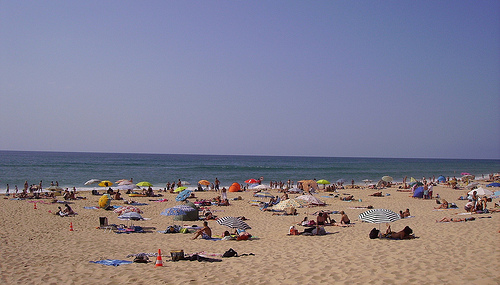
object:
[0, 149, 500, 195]
water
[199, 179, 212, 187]
umbrella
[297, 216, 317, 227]
person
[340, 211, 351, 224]
person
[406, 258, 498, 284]
sand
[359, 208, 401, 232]
umbrella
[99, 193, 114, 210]
man sitting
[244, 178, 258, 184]
umbrella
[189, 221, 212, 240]
people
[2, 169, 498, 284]
beach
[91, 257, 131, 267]
blue blanket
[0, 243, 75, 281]
sand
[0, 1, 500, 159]
clear skies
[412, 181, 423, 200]
man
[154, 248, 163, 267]
cone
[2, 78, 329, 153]
clouds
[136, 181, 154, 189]
umbrella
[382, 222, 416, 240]
man